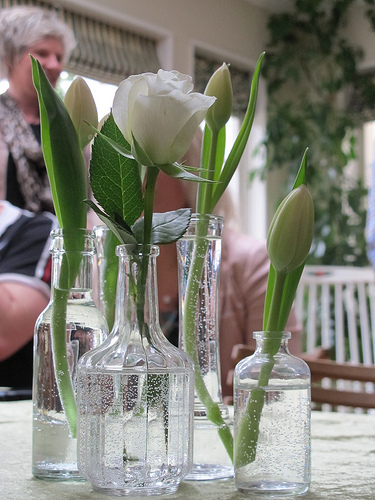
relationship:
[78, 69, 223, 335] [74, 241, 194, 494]
rose in clear vase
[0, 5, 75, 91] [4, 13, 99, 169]
head on woman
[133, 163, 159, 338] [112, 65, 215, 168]
stem of flower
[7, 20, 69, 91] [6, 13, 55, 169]
head of woman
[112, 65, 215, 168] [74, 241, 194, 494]
flower in clear vase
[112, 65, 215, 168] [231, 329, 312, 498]
flower in clear jar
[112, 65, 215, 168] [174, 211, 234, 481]
flower in clear vase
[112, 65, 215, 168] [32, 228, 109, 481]
flower in clear vase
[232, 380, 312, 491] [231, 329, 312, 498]
water in clear jar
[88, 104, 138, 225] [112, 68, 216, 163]
green leaf next to rose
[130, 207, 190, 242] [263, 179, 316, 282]
leaf next to flower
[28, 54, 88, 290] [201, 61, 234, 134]
leaf next to flower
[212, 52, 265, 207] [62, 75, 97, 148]
leaf next to rose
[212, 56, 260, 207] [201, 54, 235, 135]
leaf in flower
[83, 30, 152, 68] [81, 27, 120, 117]
blinds on window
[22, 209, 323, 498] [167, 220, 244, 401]
bottles has water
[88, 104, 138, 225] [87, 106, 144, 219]
green leaf has veins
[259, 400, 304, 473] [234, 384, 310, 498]
bubbles in water